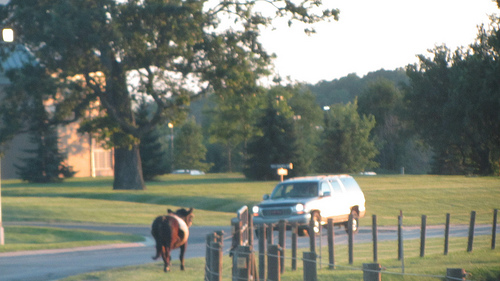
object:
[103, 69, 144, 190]
trunk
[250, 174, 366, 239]
suv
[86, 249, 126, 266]
road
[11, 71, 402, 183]
pine trees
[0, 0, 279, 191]
tall tree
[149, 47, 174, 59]
leaves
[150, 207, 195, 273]
animal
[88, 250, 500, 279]
grass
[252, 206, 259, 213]
headlights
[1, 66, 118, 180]
house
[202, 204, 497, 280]
fence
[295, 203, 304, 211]
headligh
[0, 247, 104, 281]
road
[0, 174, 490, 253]
grass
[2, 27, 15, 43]
light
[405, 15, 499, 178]
trees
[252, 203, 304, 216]
lights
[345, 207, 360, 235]
back tire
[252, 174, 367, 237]
car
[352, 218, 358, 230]
rim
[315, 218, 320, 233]
rim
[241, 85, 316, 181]
tree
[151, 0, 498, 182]
forest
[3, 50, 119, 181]
building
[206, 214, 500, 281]
pole